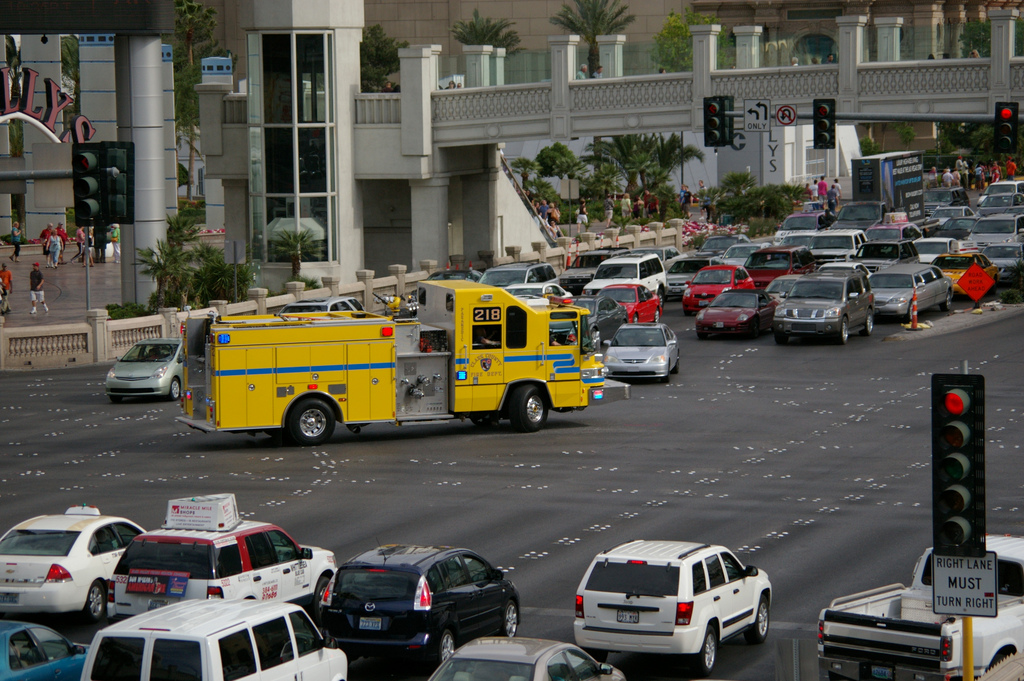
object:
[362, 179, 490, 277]
wall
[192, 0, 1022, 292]
building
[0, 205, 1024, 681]
road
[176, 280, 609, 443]
fire truck